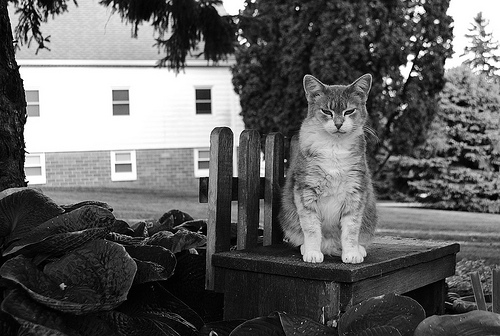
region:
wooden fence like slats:
[194, 124, 284, 295]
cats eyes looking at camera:
[316, 104, 359, 121]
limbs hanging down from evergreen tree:
[8, 0, 268, 72]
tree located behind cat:
[229, 3, 448, 230]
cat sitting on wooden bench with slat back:
[188, 77, 433, 326]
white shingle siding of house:
[15, 58, 246, 147]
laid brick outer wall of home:
[10, 143, 283, 198]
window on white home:
[103, 81, 136, 122]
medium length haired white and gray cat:
[275, 68, 385, 277]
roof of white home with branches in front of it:
[8, 1, 253, 85]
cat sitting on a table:
[211, 73, 460, 330]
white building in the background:
[6, 1, 248, 198]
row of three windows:
[25, 88, 212, 117]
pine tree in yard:
[383, 57, 497, 213]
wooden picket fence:
[203, 125, 297, 290]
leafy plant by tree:
[0, 188, 204, 333]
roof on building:
[7, 0, 250, 66]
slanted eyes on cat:
[320, 105, 357, 117]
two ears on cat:
[303, 71, 373, 101]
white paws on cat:
[301, 241, 368, 264]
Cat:
[258, 49, 445, 287]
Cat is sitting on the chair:
[240, 63, 431, 294]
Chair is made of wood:
[186, 110, 486, 322]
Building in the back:
[11, 5, 289, 208]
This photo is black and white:
[8, 23, 493, 319]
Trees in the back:
[226, 1, 491, 225]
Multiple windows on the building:
[20, 65, 248, 195]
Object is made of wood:
[173, 106, 455, 331]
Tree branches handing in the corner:
[8, 3, 264, 103]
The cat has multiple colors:
[281, 79, 396, 286]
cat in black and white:
[284, 63, 429, 268]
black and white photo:
[25, 11, 497, 313]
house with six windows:
[30, 15, 226, 216]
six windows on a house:
[15, 61, 227, 186]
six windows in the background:
[26, 70, 236, 180]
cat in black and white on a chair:
[240, 83, 481, 290]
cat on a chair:
[214, 74, 452, 284]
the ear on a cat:
[280, 70, 325, 110]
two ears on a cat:
[283, 62, 396, 93]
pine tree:
[439, 19, 496, 199]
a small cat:
[284, 72, 378, 266]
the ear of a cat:
[300, 72, 324, 98]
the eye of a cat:
[320, 108, 334, 115]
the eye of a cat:
[342, 107, 357, 117]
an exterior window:
[110, 88, 130, 114]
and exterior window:
[194, 88, 212, 115]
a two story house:
[2, 5, 246, 197]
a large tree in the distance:
[385, 64, 499, 206]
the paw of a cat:
[302, 251, 325, 263]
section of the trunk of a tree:
[0, 2, 25, 191]